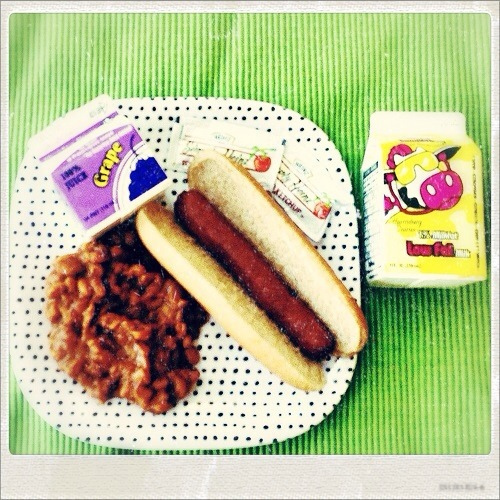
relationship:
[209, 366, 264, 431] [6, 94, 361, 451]
dots on plate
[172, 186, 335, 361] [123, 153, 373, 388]
hotdog on a bun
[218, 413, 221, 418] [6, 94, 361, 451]
dots on a plate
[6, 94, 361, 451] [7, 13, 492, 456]
plate on a placemat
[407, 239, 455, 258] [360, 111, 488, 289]
lettering on carton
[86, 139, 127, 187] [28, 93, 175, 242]
yellow lettering on carton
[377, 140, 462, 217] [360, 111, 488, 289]
cow on carton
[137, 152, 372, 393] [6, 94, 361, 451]
hotdog on plate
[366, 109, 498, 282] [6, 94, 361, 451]
milk next to plate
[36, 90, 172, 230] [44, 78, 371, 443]
juice on plate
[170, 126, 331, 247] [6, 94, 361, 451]
ketchup packages on plate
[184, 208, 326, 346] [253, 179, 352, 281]
weiner on bun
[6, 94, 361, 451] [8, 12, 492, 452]
plate on place mat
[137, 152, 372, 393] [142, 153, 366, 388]
hotdog on bun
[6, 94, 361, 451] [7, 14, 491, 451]
plate on table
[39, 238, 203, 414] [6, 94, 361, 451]
beans on plate